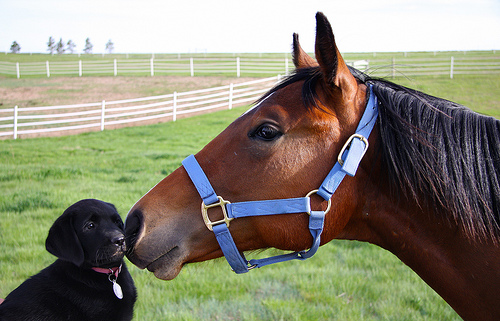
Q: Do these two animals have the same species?
A: No, they are horses and dogs.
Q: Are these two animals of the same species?
A: No, they are horses and dogs.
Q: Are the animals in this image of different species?
A: Yes, they are horses and dogs.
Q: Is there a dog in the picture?
A: Yes, there is a dog.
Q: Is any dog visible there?
A: Yes, there is a dog.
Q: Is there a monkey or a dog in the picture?
A: Yes, there is a dog.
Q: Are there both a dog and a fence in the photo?
A: Yes, there are both a dog and a fence.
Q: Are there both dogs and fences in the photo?
A: Yes, there are both a dog and a fence.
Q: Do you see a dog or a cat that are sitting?
A: Yes, the dog is sitting.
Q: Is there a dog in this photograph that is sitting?
A: Yes, there is a dog that is sitting.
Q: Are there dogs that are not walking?
A: Yes, there is a dog that is sitting.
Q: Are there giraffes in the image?
A: No, there are no giraffes.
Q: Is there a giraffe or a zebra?
A: No, there are no giraffes or zebras.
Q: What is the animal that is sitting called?
A: The animal is a dog.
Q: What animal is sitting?
A: The animal is a dog.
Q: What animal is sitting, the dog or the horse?
A: The dog is sitting.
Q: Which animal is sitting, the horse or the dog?
A: The dog is sitting.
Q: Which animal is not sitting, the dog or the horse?
A: The horse is not sitting.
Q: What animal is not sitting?
A: The animal is a horse.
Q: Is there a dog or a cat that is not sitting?
A: No, there is a dog but it is sitting.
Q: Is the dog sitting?
A: Yes, the dog is sitting.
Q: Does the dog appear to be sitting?
A: Yes, the dog is sitting.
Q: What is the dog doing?
A: The dog is sitting.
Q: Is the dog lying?
A: No, the dog is sitting.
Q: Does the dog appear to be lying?
A: No, the dog is sitting.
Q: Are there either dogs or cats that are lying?
A: No, there is a dog but it is sitting.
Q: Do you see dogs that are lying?
A: No, there is a dog but it is sitting.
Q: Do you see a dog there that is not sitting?
A: No, there is a dog but it is sitting.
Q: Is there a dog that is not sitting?
A: No, there is a dog but it is sitting.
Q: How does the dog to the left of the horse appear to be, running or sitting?
A: The dog is sitting.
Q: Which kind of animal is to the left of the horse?
A: The animal is a dog.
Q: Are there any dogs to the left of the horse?
A: Yes, there is a dog to the left of the horse.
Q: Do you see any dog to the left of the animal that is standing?
A: Yes, there is a dog to the left of the horse.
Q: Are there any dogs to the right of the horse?
A: No, the dog is to the left of the horse.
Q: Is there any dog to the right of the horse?
A: No, the dog is to the left of the horse.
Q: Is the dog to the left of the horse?
A: Yes, the dog is to the left of the horse.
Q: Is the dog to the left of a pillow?
A: No, the dog is to the left of the horse.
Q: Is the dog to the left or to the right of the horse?
A: The dog is to the left of the horse.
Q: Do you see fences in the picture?
A: Yes, there is a fence.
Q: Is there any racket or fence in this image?
A: Yes, there is a fence.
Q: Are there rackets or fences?
A: Yes, there is a fence.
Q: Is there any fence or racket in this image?
A: Yes, there is a fence.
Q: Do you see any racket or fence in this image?
A: Yes, there is a fence.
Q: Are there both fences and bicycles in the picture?
A: No, there is a fence but no bicycles.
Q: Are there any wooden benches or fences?
A: Yes, there is a wood fence.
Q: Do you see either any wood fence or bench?
A: Yes, there is a wood fence.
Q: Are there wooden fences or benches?
A: Yes, there is a wood fence.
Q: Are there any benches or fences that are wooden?
A: Yes, the fence is wooden.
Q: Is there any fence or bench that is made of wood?
A: Yes, the fence is made of wood.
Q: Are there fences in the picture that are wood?
A: Yes, there is a wood fence.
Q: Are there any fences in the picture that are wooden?
A: Yes, there is a fence that is wooden.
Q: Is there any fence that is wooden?
A: Yes, there is a fence that is wooden.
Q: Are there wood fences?
A: Yes, there is a fence that is made of wood.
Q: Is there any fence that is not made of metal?
A: Yes, there is a fence that is made of wood.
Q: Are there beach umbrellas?
A: No, there are no beach umbrellas.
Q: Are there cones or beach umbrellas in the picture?
A: No, there are no beach umbrellas or cones.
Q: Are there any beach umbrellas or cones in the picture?
A: No, there are no beach umbrellas or cones.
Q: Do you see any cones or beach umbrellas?
A: No, there are no beach umbrellas or cones.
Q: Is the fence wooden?
A: Yes, the fence is wooden.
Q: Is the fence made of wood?
A: Yes, the fence is made of wood.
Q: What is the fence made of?
A: The fence is made of wood.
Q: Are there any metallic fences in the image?
A: No, there is a fence but it is wooden.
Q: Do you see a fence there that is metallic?
A: No, there is a fence but it is wooden.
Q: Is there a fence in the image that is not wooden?
A: No, there is a fence but it is wooden.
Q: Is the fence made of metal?
A: No, the fence is made of wood.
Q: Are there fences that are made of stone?
A: No, there is a fence but it is made of wood.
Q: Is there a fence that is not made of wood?
A: No, there is a fence but it is made of wood.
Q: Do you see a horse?
A: Yes, there is a horse.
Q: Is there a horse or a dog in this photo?
A: Yes, there is a horse.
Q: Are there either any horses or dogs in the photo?
A: Yes, there is a horse.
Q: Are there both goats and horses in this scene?
A: No, there is a horse but no goats.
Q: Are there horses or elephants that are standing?
A: Yes, the horse is standing.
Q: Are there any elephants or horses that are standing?
A: Yes, the horse is standing.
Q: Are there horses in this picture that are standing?
A: Yes, there is a horse that is standing.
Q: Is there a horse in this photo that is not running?
A: Yes, there is a horse that is standing.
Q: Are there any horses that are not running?
A: Yes, there is a horse that is standing.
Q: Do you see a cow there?
A: No, there are no cows.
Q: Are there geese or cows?
A: No, there are no cows or geese.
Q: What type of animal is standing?
A: The animal is a horse.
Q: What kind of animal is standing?
A: The animal is a horse.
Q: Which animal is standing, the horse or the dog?
A: The horse is standing.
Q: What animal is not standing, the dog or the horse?
A: The dog is not standing.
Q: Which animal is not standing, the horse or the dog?
A: The dog is not standing.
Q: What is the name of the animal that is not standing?
A: The animal is a dog.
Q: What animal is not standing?
A: The animal is a dog.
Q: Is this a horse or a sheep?
A: This is a horse.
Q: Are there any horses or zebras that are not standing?
A: No, there is a horse but it is standing.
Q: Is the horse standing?
A: Yes, the horse is standing.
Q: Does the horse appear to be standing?
A: Yes, the horse is standing.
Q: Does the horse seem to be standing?
A: Yes, the horse is standing.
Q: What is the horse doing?
A: The horse is standing.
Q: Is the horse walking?
A: No, the horse is standing.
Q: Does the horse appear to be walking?
A: No, the horse is standing.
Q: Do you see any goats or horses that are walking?
A: No, there is a horse but it is standing.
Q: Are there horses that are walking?
A: No, there is a horse but it is standing.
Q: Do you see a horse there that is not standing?
A: No, there is a horse but it is standing.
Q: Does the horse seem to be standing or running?
A: The horse is standing.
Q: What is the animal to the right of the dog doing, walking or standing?
A: The horse is standing.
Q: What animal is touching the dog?
A: The animal is a horse.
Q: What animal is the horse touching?
A: The horse is touching the dog.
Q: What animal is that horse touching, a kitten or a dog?
A: The horse is touching a dog.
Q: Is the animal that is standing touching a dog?
A: Yes, the horse is touching a dog.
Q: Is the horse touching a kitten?
A: No, the horse is touching a dog.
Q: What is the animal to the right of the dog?
A: The animal is a horse.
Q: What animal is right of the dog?
A: The animal is a horse.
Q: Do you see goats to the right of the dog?
A: No, there is a horse to the right of the dog.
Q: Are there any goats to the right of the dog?
A: No, there is a horse to the right of the dog.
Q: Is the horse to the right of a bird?
A: No, the horse is to the right of a dog.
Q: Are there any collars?
A: Yes, there is a collar.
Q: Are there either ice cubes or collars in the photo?
A: Yes, there is a collar.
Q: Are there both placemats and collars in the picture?
A: No, there is a collar but no placemats.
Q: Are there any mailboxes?
A: No, there are no mailboxes.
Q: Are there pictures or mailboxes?
A: No, there are no mailboxes or pictures.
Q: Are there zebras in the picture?
A: No, there are no zebras.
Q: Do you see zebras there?
A: No, there are no zebras.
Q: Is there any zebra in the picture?
A: No, there are no zebras.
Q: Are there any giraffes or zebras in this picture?
A: No, there are no zebras or giraffes.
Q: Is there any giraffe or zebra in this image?
A: No, there are no zebras or giraffes.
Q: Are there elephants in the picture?
A: No, there are no elephants.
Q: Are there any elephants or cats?
A: No, there are no elephants or cats.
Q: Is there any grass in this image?
A: Yes, there is grass.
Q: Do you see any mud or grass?
A: Yes, there is grass.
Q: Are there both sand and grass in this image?
A: No, there is grass but no sand.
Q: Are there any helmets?
A: No, there are no helmets.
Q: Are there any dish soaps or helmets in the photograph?
A: No, there are no helmets or dish soaps.